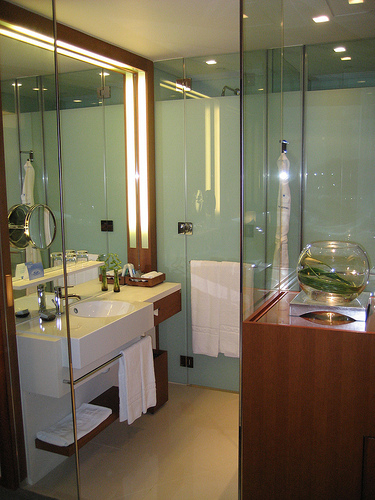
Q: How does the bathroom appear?
A: Neat and tidy.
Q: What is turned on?
A: Lights.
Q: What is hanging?
A: Towels.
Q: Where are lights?
A: On the ceiling.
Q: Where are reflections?
A: On the mirror.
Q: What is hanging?
A: White towels.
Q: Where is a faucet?
A: Over a sink.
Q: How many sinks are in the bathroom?
A: One.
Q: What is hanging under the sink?
A: A towel.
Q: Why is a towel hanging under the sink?
A: To dry hands.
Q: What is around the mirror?
A: Lights.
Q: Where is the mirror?
A: In front of the sink.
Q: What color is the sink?
A: White.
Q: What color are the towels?
A: White.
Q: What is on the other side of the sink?
A: A shower.